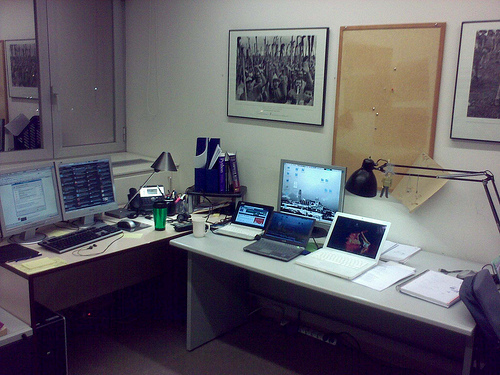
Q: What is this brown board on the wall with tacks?
A: Bulletin board.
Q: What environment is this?
A: Office.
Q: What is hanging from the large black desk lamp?
A: Figurine.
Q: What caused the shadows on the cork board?
A: Papers.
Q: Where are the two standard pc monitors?
A: On the left.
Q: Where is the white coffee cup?
A: Corner of the two counters.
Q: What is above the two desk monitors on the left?
A: Cabinet.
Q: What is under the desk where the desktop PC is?
A: CPU.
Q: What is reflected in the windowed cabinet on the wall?
A: Framed print.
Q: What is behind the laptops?
A: Monitor.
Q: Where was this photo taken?
A: In office.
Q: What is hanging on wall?
A: Frames and board.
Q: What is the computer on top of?
A: Desk.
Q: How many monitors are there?
A: 3.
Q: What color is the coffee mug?
A: White.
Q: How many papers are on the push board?
A: 1.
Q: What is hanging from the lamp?
A: Doll.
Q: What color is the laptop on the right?
A: White.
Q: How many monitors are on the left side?
A: 2.